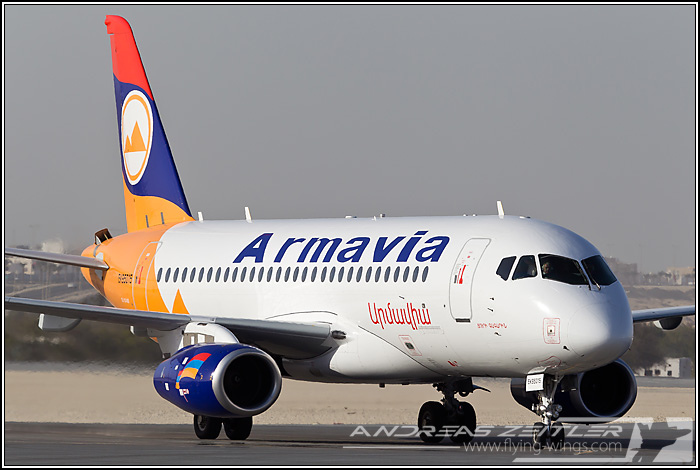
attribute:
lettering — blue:
[226, 225, 452, 263]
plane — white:
[0, 15, 700, 451]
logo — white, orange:
[75, 87, 184, 191]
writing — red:
[362, 292, 434, 335]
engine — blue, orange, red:
[148, 333, 295, 419]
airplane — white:
[12, 5, 531, 446]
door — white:
[445, 228, 493, 326]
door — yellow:
[114, 233, 145, 304]